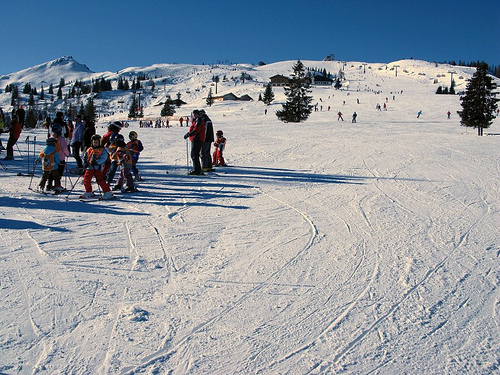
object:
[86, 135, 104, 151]
head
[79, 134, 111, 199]
child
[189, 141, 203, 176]
pants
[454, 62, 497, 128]
leaves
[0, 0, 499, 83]
sky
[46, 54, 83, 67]
peak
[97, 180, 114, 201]
boots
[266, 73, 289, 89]
house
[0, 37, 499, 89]
distance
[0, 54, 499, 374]
snow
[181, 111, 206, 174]
people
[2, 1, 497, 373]
picture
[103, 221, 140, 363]
lines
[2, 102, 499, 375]
ground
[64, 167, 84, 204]
stick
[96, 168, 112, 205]
legs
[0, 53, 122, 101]
hill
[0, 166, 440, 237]
shadow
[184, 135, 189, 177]
poles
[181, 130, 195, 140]
hand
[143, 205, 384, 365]
markings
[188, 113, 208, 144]
jacket